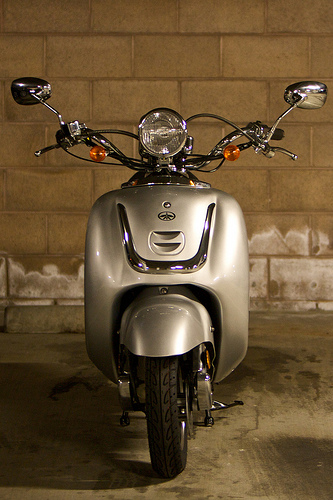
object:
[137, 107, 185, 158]
headlight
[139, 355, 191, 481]
tire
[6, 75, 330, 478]
motorcycle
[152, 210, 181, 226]
symbol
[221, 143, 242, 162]
light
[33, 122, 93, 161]
handlebar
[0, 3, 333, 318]
cinder blocks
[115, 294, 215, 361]
fender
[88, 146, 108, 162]
signal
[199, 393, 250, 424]
kickstand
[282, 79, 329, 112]
mirror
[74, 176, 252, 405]
trim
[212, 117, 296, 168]
break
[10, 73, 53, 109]
mirror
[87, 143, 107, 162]
light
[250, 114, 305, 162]
handlebar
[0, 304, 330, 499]
ground